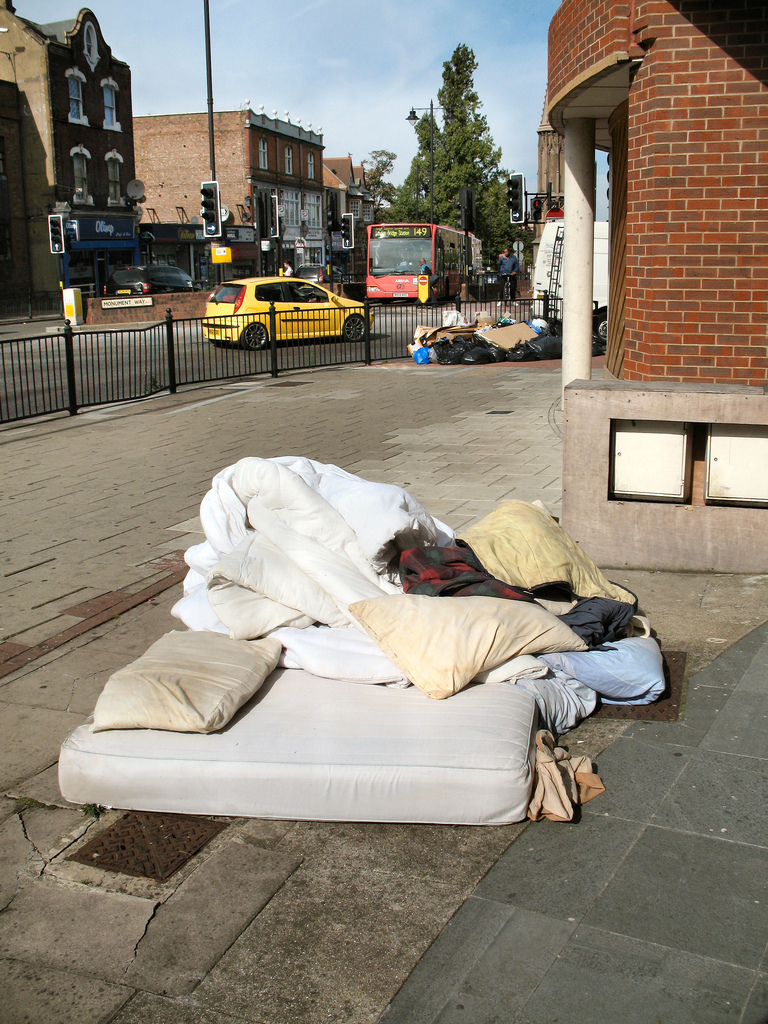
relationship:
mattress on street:
[31, 600, 592, 847] [0, 400, 758, 1022]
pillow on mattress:
[77, 621, 287, 742] [57, 624, 549, 844]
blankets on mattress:
[190, 442, 631, 712] [57, 624, 549, 844]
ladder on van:
[542, 224, 572, 330] [507, 191, 611, 327]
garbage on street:
[395, 282, 614, 383] [0, 400, 758, 1022]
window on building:
[58, 60, 88, 127] [10, 8, 145, 299]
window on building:
[78, 21, 108, 76] [3, 3, 173, 282]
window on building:
[65, 140, 102, 207] [0, 8, 167, 320]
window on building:
[254, 126, 276, 181] [133, 99, 349, 276]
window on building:
[300, 149, 320, 183] [114, 92, 331, 267]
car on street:
[190, 271, 395, 357] [10, 293, 550, 421]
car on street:
[114, 254, 208, 295] [0, 267, 538, 424]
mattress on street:
[31, 600, 592, 847] [0, 310, 758, 1020]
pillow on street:
[77, 620, 287, 741] [0, 310, 758, 1020]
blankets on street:
[190, 443, 401, 586] [0, 310, 758, 1020]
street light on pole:
[194, 172, 227, 251] [198, 4, 227, 239]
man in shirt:
[491, 243, 523, 311] [475, 271, 501, 300]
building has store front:
[0, 8, 167, 320] [39, 14, 159, 317]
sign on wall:
[97, 294, 154, 312] [76, 287, 210, 321]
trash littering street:
[59, 453, 669, 825] [0, 400, 758, 1022]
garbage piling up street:
[407, 310, 613, 363] [0, 400, 758, 1022]